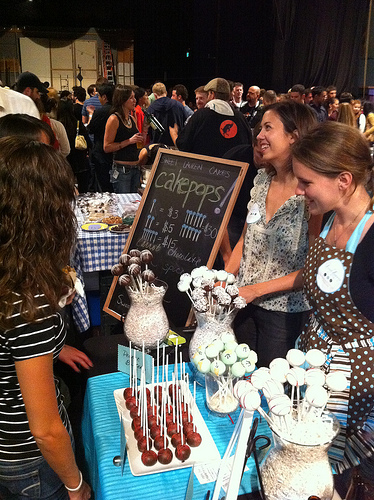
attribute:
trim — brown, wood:
[156, 144, 247, 169]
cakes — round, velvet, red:
[122, 334, 209, 474]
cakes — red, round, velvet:
[123, 382, 205, 469]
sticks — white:
[124, 335, 200, 445]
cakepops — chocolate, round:
[108, 245, 156, 287]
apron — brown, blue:
[298, 233, 361, 466]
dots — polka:
[317, 303, 358, 338]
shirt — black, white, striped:
[3, 290, 76, 487]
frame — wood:
[100, 148, 250, 337]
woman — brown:
[273, 125, 362, 482]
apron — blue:
[296, 216, 362, 465]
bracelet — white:
[64, 472, 85, 489]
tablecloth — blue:
[78, 364, 262, 498]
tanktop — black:
[112, 117, 138, 159]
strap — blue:
[317, 216, 334, 240]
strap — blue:
[338, 213, 362, 259]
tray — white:
[113, 378, 223, 475]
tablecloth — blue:
[79, 354, 280, 496]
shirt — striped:
[1, 146, 98, 498]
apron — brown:
[281, 216, 370, 449]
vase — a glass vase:
[241, 401, 365, 498]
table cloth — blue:
[78, 342, 247, 498]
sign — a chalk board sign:
[101, 148, 232, 348]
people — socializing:
[10, 55, 373, 460]